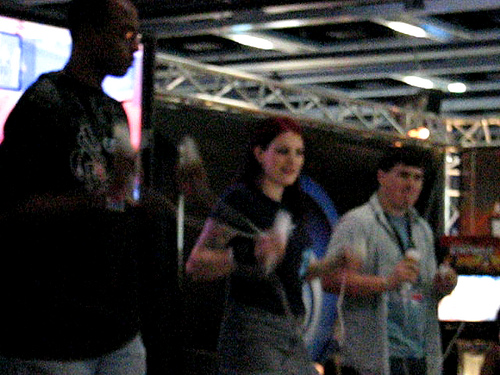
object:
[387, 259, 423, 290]
hands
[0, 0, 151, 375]
person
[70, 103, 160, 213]
brandings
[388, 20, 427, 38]
lighting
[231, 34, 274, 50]
lighting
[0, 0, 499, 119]
roof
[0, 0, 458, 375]
three people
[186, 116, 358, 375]
lady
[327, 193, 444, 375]
shirt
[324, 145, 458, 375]
person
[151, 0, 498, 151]
metal frame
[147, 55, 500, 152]
railing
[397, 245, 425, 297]
controller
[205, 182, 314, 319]
shirt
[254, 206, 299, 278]
controller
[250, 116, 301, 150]
hair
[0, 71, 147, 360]
shirt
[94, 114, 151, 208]
wii